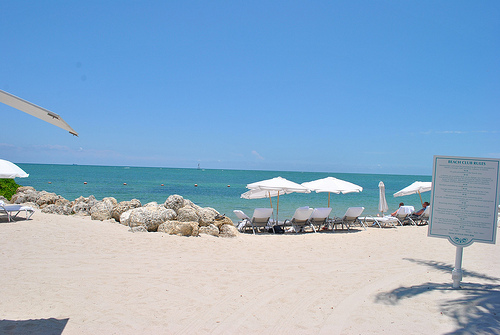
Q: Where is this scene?
A: Resort.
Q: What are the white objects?
A: Umbrellas.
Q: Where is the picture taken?
A: Beach.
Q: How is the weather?
A: Sunny.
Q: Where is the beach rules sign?
A: Under the shade from the tree.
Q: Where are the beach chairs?
A: Under the umbrellas.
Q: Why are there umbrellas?
A: To shade people from the sun.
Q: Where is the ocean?
A: In the distance.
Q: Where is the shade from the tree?
A: Over the beach rules sign.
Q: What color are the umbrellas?
A: White.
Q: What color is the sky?
A: Blue.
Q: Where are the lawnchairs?
A: The sand.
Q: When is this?
A: Daytime.